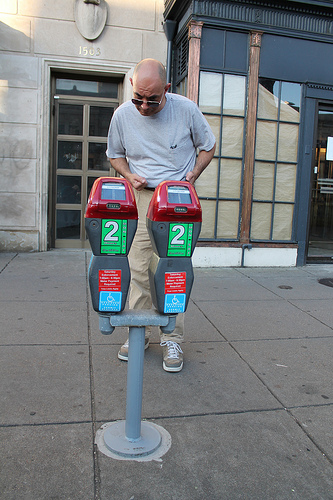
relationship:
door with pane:
[49, 92, 123, 250] [54, 101, 89, 136]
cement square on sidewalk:
[2, 263, 87, 304] [1, 252, 331, 499]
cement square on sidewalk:
[0, 343, 91, 423] [1, 252, 331, 499]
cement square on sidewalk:
[97, 411, 331, 498] [1, 252, 331, 499]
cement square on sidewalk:
[192, 267, 281, 301] [1, 252, 331, 499]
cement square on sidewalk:
[231, 335, 332, 412] [1, 252, 331, 499]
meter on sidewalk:
[83, 176, 138, 335] [13, 373, 330, 485]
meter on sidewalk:
[145, 180, 202, 334] [13, 373, 330, 485]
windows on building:
[249, 77, 300, 241] [97, 7, 331, 257]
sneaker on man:
[160, 333, 184, 372] [104, 58, 218, 371]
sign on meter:
[163, 292, 184, 313] [146, 180, 203, 332]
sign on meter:
[97, 288, 122, 312] [82, 176, 137, 333]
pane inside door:
[51, 207, 80, 252] [48, 71, 123, 249]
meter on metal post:
[83, 176, 138, 335] [94, 314, 178, 459]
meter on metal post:
[145, 180, 202, 334] [94, 314, 178, 459]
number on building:
[76, 43, 101, 57] [7, 8, 331, 272]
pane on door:
[59, 101, 83, 134] [51, 67, 128, 257]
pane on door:
[50, 140, 77, 174] [3, 20, 145, 256]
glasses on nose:
[129, 87, 166, 109] [140, 99, 147, 111]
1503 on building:
[79, 46, 100, 57] [7, 0, 108, 226]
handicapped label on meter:
[160, 293, 187, 314] [146, 180, 203, 332]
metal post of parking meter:
[125, 326, 145, 441] [80, 174, 203, 321]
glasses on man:
[131, 88, 166, 107] [99, 51, 220, 380]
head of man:
[125, 56, 171, 117] [104, 58, 218, 371]